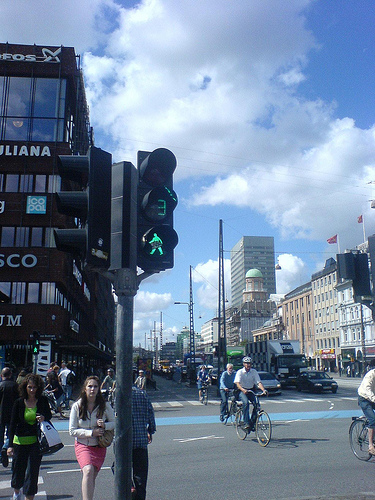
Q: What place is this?
A: It is a street.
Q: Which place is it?
A: It is a street.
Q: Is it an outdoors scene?
A: Yes, it is outdoors.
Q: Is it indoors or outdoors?
A: It is outdoors.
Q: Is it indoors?
A: No, it is outdoors.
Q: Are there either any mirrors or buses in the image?
A: No, there are no buses or mirrors.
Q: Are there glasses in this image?
A: No, there are no glasses.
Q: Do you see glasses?
A: No, there are no glasses.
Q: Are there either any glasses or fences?
A: No, there are no glasses or fences.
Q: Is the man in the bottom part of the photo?
A: Yes, the man is in the bottom of the image.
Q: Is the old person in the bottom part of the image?
A: Yes, the man is in the bottom of the image.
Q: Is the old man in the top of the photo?
A: No, the man is in the bottom of the image.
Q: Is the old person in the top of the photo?
A: No, the man is in the bottom of the image.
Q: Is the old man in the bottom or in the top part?
A: The man is in the bottom of the image.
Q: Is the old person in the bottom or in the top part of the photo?
A: The man is in the bottom of the image.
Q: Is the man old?
A: Yes, the man is old.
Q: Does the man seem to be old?
A: Yes, the man is old.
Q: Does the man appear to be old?
A: Yes, the man is old.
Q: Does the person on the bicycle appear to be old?
A: Yes, the man is old.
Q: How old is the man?
A: The man is old.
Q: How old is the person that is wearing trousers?
A: The man is old.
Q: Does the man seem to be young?
A: No, the man is old.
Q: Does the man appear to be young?
A: No, the man is old.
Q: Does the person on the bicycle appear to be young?
A: No, the man is old.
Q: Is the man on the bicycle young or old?
A: The man is old.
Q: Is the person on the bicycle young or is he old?
A: The man is old.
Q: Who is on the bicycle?
A: The man is on the bicycle.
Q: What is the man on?
A: The man is on the bicycle.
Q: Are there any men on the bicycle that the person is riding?
A: Yes, there is a man on the bicycle.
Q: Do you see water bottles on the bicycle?
A: No, there is a man on the bicycle.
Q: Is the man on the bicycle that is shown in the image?
A: Yes, the man is on the bicycle.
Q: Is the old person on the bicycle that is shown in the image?
A: Yes, the man is on the bicycle.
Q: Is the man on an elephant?
A: No, the man is on the bicycle.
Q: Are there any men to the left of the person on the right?
A: Yes, there is a man to the left of the person.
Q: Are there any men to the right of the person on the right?
A: No, the man is to the left of the person.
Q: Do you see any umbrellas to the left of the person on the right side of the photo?
A: No, there is a man to the left of the person.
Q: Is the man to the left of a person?
A: Yes, the man is to the left of a person.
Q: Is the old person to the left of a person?
A: Yes, the man is to the left of a person.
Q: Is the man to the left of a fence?
A: No, the man is to the left of a person.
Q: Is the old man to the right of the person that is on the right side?
A: No, the man is to the left of the person.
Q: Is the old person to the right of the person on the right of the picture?
A: No, the man is to the left of the person.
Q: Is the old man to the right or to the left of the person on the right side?
A: The man is to the left of the person.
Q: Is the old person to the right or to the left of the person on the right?
A: The man is to the left of the person.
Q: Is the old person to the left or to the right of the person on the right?
A: The man is to the left of the person.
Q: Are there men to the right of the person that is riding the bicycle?
A: Yes, there is a man to the right of the person.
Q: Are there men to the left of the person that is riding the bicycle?
A: No, the man is to the right of the person.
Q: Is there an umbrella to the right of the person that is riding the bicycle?
A: No, there is a man to the right of the person.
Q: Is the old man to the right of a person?
A: Yes, the man is to the right of a person.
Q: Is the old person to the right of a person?
A: Yes, the man is to the right of a person.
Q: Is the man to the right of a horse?
A: No, the man is to the right of a person.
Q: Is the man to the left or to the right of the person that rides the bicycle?
A: The man is to the right of the person.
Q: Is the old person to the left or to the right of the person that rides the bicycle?
A: The man is to the right of the person.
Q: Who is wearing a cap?
A: The man is wearing a cap.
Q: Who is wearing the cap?
A: The man is wearing a cap.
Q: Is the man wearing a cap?
A: Yes, the man is wearing a cap.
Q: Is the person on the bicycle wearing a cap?
A: Yes, the man is wearing a cap.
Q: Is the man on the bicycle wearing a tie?
A: No, the man is wearing a cap.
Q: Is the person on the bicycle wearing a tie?
A: No, the man is wearing a cap.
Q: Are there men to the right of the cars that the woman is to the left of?
A: Yes, there is a man to the right of the cars.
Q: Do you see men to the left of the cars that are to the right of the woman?
A: No, the man is to the right of the cars.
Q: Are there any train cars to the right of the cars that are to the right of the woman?
A: No, there is a man to the right of the cars.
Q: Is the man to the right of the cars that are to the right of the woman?
A: Yes, the man is to the right of the cars.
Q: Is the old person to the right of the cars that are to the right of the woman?
A: Yes, the man is to the right of the cars.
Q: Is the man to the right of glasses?
A: No, the man is to the right of the cars.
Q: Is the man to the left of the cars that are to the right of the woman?
A: No, the man is to the right of the cars.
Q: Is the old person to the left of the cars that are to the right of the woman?
A: No, the man is to the right of the cars.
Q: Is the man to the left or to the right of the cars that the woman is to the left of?
A: The man is to the right of the cars.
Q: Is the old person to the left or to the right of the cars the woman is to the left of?
A: The man is to the right of the cars.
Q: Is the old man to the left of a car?
A: Yes, the man is to the left of a car.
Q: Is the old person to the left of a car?
A: Yes, the man is to the left of a car.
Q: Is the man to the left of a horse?
A: No, the man is to the left of a car.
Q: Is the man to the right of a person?
A: Yes, the man is to the right of a person.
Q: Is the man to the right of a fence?
A: No, the man is to the right of a person.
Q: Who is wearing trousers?
A: The man is wearing trousers.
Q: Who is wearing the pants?
A: The man is wearing trousers.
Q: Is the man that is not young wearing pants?
A: Yes, the man is wearing pants.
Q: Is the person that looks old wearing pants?
A: Yes, the man is wearing pants.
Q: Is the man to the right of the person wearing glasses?
A: No, the man is wearing pants.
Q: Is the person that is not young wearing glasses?
A: No, the man is wearing pants.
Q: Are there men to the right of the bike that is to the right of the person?
A: Yes, there is a man to the right of the bike.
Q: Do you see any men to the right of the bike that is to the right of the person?
A: Yes, there is a man to the right of the bike.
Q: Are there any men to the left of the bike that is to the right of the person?
A: No, the man is to the right of the bike.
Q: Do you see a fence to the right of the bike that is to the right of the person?
A: No, there is a man to the right of the bike.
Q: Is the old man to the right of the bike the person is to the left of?
A: Yes, the man is to the right of the bike.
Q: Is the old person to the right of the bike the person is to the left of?
A: Yes, the man is to the right of the bike.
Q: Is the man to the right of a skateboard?
A: No, the man is to the right of the bike.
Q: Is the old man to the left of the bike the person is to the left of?
A: No, the man is to the right of the bike.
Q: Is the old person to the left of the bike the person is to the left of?
A: No, the man is to the right of the bike.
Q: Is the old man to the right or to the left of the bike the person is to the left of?
A: The man is to the right of the bike.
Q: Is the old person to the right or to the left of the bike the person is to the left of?
A: The man is to the right of the bike.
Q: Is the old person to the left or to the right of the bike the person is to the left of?
A: The man is to the right of the bike.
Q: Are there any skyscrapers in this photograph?
A: Yes, there is a skyscraper.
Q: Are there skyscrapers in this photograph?
A: Yes, there is a skyscraper.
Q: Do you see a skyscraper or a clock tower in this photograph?
A: Yes, there is a skyscraper.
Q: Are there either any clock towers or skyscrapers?
A: Yes, there is a skyscraper.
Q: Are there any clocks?
A: No, there are no clocks.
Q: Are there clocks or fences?
A: No, there are no clocks or fences.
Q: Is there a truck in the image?
A: Yes, there is a truck.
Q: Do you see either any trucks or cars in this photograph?
A: Yes, there is a truck.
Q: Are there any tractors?
A: No, there are no tractors.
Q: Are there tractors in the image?
A: No, there are no tractors.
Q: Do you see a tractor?
A: No, there are no tractors.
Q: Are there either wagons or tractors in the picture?
A: No, there are no tractors or wagons.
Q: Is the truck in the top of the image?
A: No, the truck is in the bottom of the image.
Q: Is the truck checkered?
A: Yes, the truck is checkered.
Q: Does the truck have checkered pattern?
A: Yes, the truck is checkered.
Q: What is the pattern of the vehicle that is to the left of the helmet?
A: The truck is checkered.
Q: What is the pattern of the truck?
A: The truck is checkered.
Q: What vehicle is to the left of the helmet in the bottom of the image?
A: The vehicle is a truck.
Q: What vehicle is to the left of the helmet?
A: The vehicle is a truck.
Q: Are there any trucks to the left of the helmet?
A: Yes, there is a truck to the left of the helmet.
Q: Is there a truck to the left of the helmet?
A: Yes, there is a truck to the left of the helmet.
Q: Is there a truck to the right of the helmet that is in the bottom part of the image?
A: No, the truck is to the left of the helmet.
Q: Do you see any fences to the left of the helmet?
A: No, there is a truck to the left of the helmet.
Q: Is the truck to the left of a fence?
A: No, the truck is to the left of the helmet.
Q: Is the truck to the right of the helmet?
A: No, the truck is to the left of the helmet.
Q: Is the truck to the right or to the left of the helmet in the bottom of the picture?
A: The truck is to the left of the helmet.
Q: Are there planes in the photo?
A: No, there are no planes.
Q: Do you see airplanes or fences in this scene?
A: No, there are no airplanes or fences.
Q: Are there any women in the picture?
A: Yes, there is a woman.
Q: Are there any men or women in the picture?
A: Yes, there is a woman.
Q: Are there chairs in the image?
A: No, there are no chairs.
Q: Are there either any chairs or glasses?
A: No, there are no chairs or glasses.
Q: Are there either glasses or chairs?
A: No, there are no chairs or glasses.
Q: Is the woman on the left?
A: Yes, the woman is on the left of the image.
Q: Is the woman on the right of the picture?
A: No, the woman is on the left of the image.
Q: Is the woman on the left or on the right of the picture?
A: The woman is on the left of the image.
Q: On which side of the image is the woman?
A: The woman is on the left of the image.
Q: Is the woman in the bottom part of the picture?
A: Yes, the woman is in the bottom of the image.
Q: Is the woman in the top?
A: No, the woman is in the bottom of the image.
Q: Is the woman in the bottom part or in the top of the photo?
A: The woman is in the bottom of the image.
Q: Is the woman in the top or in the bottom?
A: The woman is in the bottom of the image.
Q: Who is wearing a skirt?
A: The woman is wearing a skirt.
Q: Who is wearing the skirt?
A: The woman is wearing a skirt.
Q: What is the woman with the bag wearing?
A: The woman is wearing a skirt.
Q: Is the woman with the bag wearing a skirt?
A: Yes, the woman is wearing a skirt.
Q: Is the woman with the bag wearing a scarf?
A: No, the woman is wearing a skirt.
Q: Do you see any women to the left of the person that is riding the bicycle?
A: Yes, there is a woman to the left of the person.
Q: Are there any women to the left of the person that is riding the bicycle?
A: Yes, there is a woman to the left of the person.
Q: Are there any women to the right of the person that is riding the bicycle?
A: No, the woman is to the left of the person.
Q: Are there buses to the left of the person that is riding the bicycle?
A: No, there is a woman to the left of the person.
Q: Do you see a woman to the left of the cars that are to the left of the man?
A: Yes, there is a woman to the left of the cars.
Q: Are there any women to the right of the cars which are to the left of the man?
A: No, the woman is to the left of the cars.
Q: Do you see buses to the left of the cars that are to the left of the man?
A: No, there is a woman to the left of the cars.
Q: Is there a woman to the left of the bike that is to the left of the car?
A: Yes, there is a woman to the left of the bike.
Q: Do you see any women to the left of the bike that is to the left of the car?
A: Yes, there is a woman to the left of the bike.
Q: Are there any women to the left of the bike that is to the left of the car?
A: Yes, there is a woman to the left of the bike.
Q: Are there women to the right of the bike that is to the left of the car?
A: No, the woman is to the left of the bike.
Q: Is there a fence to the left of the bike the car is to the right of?
A: No, there is a woman to the left of the bike.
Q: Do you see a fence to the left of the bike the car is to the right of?
A: No, there is a woman to the left of the bike.